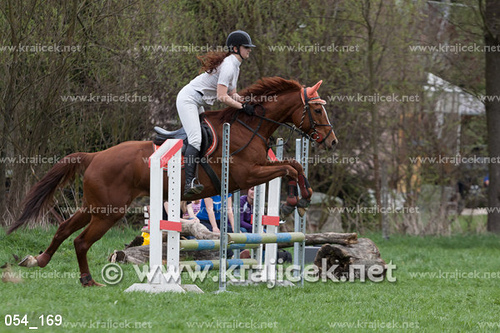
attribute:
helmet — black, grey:
[227, 37, 248, 56]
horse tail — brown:
[9, 160, 89, 202]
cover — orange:
[292, 75, 334, 99]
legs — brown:
[254, 144, 325, 217]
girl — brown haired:
[130, 33, 272, 155]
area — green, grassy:
[42, 255, 212, 298]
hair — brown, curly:
[187, 45, 250, 83]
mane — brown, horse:
[237, 74, 295, 104]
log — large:
[309, 229, 400, 291]